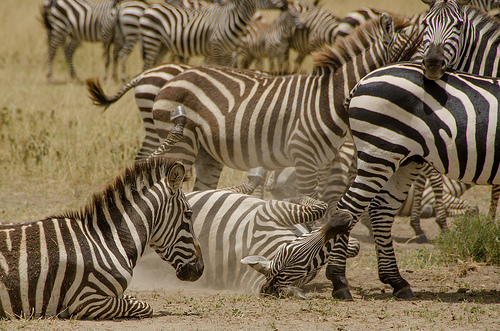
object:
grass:
[436, 209, 499, 265]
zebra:
[182, 180, 357, 299]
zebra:
[153, 11, 407, 198]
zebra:
[139, 0, 288, 73]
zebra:
[2, 154, 206, 321]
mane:
[310, 16, 412, 72]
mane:
[52, 157, 190, 218]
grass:
[0, 84, 110, 181]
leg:
[325, 149, 407, 267]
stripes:
[349, 65, 499, 185]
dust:
[126, 251, 267, 297]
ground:
[187, 298, 497, 331]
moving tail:
[84, 74, 143, 115]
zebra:
[417, 0, 470, 83]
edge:
[331, 286, 354, 303]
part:
[409, 298, 499, 325]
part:
[78, 271, 154, 320]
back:
[194, 242, 270, 287]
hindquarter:
[344, 62, 425, 146]